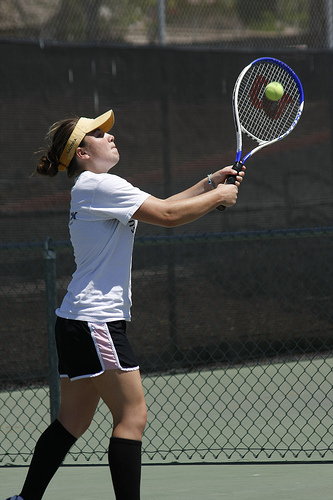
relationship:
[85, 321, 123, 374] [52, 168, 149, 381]
strip on shorts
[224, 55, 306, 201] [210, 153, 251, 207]
racket held by hands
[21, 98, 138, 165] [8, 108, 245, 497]
cap worn by lady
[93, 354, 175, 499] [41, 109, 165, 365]
leg apart of lady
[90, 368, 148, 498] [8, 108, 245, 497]
leg apart of lady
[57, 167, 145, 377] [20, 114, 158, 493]
dress worn by woman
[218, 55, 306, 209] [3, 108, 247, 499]
racquet held by woman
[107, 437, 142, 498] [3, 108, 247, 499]
black socks are worn by woman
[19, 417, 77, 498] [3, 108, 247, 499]
black socks are worn by woman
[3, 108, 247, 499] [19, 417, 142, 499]
woman wearing socks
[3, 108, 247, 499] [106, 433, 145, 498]
woman wearing socks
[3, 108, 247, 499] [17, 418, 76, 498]
woman wearing socks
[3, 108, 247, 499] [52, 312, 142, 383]
woman wearing shorts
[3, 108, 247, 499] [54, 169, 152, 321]
woman wearing shirt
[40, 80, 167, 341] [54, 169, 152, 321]
woman wearing shirt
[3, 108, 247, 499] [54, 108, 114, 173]
woman wearing visor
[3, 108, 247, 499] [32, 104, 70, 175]
woman has hair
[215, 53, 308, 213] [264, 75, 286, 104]
tennis bat with ball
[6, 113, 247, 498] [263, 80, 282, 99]
player holding ball